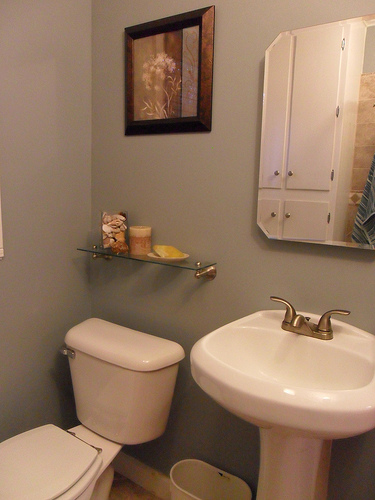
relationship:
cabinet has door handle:
[285, 25, 345, 191] [287, 170, 294, 177]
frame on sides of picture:
[123, 3, 215, 138] [131, 23, 201, 122]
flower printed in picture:
[167, 60, 177, 74] [131, 23, 201, 122]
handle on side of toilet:
[57, 345, 77, 359] [0, 316, 186, 500]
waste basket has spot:
[168, 458, 254, 500] [217, 471, 224, 479]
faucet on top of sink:
[268, 295, 350, 342] [189, 308, 374, 442]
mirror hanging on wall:
[333, 19, 373, 248] [93, 1, 375, 500]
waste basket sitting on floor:
[168, 458, 254, 500] [105, 469, 162, 499]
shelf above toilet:
[75, 243, 217, 281] [0, 316, 186, 500]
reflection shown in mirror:
[343, 73, 375, 246] [333, 19, 373, 248]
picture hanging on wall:
[131, 23, 201, 122] [93, 1, 375, 500]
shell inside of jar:
[102, 224, 112, 234] [99, 208, 129, 251]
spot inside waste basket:
[217, 471, 224, 479] [168, 458, 254, 500]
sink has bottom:
[189, 308, 374, 442] [228, 356, 351, 393]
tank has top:
[61, 317, 186, 445] [63, 316, 185, 374]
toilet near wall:
[0, 316, 186, 500] [93, 1, 375, 500]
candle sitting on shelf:
[126, 225, 153, 257] [75, 243, 217, 281]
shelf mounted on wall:
[75, 243, 217, 281] [93, 1, 375, 500]